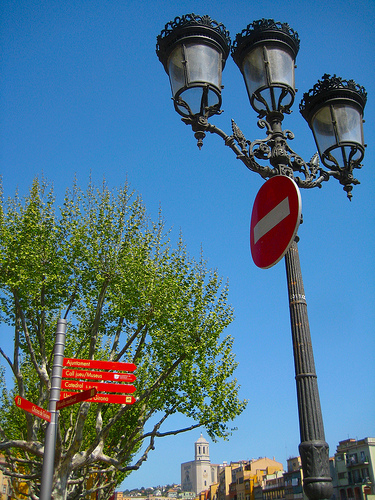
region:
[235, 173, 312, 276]
street sign on a pole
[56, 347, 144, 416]
street signs on the road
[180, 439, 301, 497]
buildings in the distance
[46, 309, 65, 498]
metal pole where signs are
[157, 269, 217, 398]
green leaves on trees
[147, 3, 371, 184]
three street lights on pole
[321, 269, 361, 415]
blue sky in the distance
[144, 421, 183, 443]
branches of a tree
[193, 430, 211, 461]
top of a building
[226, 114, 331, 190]
decorative scrollwork on a lamp post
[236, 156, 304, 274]
red and white sign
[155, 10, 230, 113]
black lamp post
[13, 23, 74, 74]
white clouds in blue sky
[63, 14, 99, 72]
white clouds in blue sky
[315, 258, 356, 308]
white clouds in blue sky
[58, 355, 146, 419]
red sign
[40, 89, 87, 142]
white clouds in blue sky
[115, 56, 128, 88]
white clouds in blue sky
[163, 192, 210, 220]
white clouds in blue sky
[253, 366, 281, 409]
white clouds in blue sky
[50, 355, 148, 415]
red and white sign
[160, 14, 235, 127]
gray light post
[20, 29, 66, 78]
blue sky with no clouds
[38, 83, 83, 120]
blue sky with no clouds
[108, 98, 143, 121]
blue sky with no clouds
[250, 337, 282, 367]
blue sky with no clouds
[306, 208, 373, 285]
blue sky with no clouds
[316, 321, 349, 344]
blue sky with no clouds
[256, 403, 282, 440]
blue sky with no clouds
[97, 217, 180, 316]
leaves on the tree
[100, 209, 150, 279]
the leaves are green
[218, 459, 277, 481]
buildings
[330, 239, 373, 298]
the sky is clear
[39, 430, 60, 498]
a metal pole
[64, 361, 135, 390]
a red street signs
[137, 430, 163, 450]
the tree branches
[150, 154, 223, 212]
a clear blue sky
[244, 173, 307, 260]
a red and white sign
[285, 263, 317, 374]
a grey pole